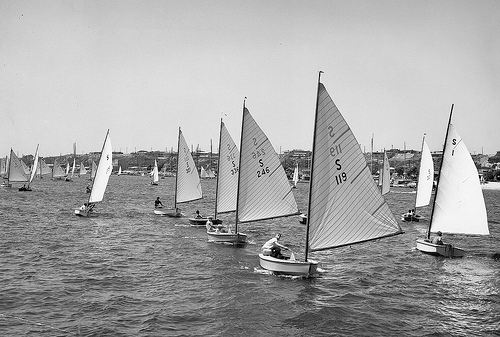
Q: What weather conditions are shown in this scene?
A: It is cloudless.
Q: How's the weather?
A: It is cloudless.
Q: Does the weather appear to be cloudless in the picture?
A: Yes, it is cloudless.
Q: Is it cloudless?
A: Yes, it is cloudless.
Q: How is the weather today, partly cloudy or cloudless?
A: It is cloudless.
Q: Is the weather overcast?
A: No, it is cloudless.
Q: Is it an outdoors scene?
A: Yes, it is outdoors.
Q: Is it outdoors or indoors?
A: It is outdoors.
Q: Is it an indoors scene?
A: No, it is outdoors.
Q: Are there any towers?
A: No, there are no towers.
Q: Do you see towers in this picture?
A: No, there are no towers.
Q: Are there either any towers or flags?
A: No, there are no towers or flags.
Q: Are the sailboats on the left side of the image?
A: Yes, the sailboats are on the left of the image.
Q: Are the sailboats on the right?
A: No, the sailboats are on the left of the image.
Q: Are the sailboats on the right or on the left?
A: The sailboats are on the left of the image.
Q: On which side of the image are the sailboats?
A: The sailboats are on the left of the image.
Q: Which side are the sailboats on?
A: The sailboats are on the left of the image.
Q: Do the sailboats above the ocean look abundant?
A: Yes, the sailboats are abundant.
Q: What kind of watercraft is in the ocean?
A: The watercraft is sailboats.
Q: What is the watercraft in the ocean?
A: The watercraft is sailboats.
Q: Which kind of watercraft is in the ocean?
A: The watercraft is sailboats.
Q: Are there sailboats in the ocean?
A: Yes, there are sailboats in the ocean.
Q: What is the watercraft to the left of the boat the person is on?
A: The watercraft is sailboats.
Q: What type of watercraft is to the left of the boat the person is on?
A: The watercraft is sailboats.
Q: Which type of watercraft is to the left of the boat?
A: The watercraft is sailboats.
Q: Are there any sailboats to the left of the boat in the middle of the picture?
A: Yes, there are sailboats to the left of the boat.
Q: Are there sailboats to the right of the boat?
A: No, the sailboats are to the left of the boat.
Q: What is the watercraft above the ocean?
A: The watercraft is sailboats.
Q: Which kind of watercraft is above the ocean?
A: The watercraft is sailboats.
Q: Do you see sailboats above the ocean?
A: Yes, there are sailboats above the ocean.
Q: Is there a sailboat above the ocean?
A: Yes, there are sailboats above the ocean.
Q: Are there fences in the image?
A: No, there are no fences.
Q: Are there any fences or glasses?
A: No, there are no fences or glasses.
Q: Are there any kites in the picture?
A: No, there are no kites.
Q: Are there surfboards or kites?
A: No, there are no kites or surfboards.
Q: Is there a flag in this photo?
A: No, there are no flags.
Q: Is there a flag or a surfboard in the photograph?
A: No, there are no flags or surfboards.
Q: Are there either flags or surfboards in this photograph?
A: No, there are no flags or surfboards.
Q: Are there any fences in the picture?
A: No, there are no fences.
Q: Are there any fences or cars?
A: No, there are no fences or cars.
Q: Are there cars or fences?
A: No, there are no fences or cars.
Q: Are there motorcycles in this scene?
A: No, there are no motorcycles.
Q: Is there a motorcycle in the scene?
A: No, there are no motorcycles.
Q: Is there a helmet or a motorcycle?
A: No, there are no motorcycles or helmets.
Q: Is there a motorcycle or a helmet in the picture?
A: No, there are no motorcycles or helmets.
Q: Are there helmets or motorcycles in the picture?
A: No, there are no motorcycles or helmets.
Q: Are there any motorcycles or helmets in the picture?
A: No, there are no motorcycles or helmets.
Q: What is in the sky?
A: The clouds are in the sky.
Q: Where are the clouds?
A: The clouds are in the sky.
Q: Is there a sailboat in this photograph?
A: Yes, there is a sailboat.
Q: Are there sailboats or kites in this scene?
A: Yes, there is a sailboat.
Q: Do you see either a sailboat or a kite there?
A: Yes, there is a sailboat.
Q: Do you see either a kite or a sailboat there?
A: Yes, there is a sailboat.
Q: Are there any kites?
A: No, there are no kites.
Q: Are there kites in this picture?
A: No, there are no kites.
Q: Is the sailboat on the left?
A: Yes, the sailboat is on the left of the image.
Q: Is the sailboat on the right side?
A: No, the sailboat is on the left of the image.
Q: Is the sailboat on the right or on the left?
A: The sailboat is on the left of the image.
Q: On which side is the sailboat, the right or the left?
A: The sailboat is on the left of the image.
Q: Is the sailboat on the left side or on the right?
A: The sailboat is on the left of the image.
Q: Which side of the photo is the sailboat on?
A: The sailboat is on the left of the image.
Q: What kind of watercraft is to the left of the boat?
A: The watercraft is a sailboat.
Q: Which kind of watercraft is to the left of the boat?
A: The watercraft is a sailboat.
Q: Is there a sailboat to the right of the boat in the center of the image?
A: No, the sailboat is to the left of the boat.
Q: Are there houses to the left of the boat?
A: No, there is a sailboat to the left of the boat.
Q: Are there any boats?
A: Yes, there is a boat.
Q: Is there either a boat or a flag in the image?
A: Yes, there is a boat.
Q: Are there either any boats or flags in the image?
A: Yes, there is a boat.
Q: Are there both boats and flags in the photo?
A: No, there is a boat but no flags.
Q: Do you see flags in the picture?
A: No, there are no flags.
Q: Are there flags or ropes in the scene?
A: No, there are no flags or ropes.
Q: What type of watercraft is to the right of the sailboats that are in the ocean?
A: The watercraft is a boat.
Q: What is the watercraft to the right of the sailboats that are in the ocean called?
A: The watercraft is a boat.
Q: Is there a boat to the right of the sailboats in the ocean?
A: Yes, there is a boat to the right of the sailboats.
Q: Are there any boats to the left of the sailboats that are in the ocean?
A: No, the boat is to the right of the sailboats.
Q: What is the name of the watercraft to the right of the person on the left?
A: The watercraft is a boat.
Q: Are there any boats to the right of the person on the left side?
A: Yes, there is a boat to the right of the person.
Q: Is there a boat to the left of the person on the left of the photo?
A: No, the boat is to the right of the person.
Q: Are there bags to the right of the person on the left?
A: No, there is a boat to the right of the person.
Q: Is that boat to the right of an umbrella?
A: No, the boat is to the right of the person.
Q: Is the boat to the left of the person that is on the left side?
A: No, the boat is to the right of the person.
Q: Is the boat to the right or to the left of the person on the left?
A: The boat is to the right of the person.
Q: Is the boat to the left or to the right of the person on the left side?
A: The boat is to the right of the person.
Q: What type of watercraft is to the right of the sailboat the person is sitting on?
A: The watercraft is a boat.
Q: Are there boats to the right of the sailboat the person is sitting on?
A: Yes, there is a boat to the right of the sailboat.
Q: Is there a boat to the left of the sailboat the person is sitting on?
A: No, the boat is to the right of the sailboat.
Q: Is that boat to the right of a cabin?
A: No, the boat is to the right of a sailboat.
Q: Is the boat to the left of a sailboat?
A: No, the boat is to the right of a sailboat.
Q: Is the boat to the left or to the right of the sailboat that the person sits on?
A: The boat is to the right of the sailboat.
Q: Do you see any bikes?
A: No, there are no bikes.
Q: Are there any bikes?
A: No, there are no bikes.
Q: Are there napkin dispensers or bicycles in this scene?
A: No, there are no bicycles or napkin dispensers.